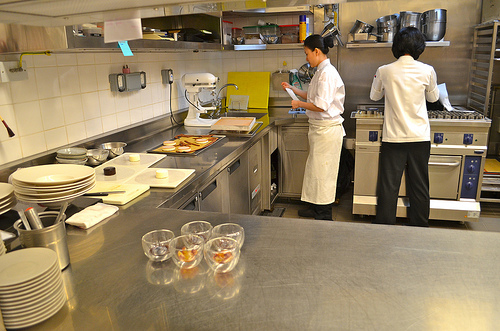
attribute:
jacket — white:
[372, 63, 469, 148]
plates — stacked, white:
[9, 162, 97, 205]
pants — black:
[373, 140, 431, 225]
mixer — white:
[181, 70, 222, 128]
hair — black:
[301, 27, 336, 49]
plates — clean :
[0, 247, 68, 329]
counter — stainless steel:
[7, 135, 498, 329]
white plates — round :
[21, 243, 68, 328]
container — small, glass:
[140, 227, 175, 262]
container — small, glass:
[169, 233, 207, 270]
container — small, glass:
[205, 236, 242, 276]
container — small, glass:
[181, 217, 211, 247]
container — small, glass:
[214, 220, 245, 247]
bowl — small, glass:
[138, 228, 176, 262]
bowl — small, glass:
[167, 235, 207, 268]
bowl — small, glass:
[204, 237, 241, 274]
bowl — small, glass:
[212, 220, 245, 245]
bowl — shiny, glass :
[139, 227, 176, 264]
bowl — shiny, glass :
[168, 234, 203, 269]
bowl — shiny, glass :
[199, 236, 242, 272]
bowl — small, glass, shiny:
[180, 219, 211, 241]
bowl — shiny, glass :
[211, 219, 245, 249]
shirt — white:
[369, 56, 439, 143]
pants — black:
[376, 142, 432, 229]